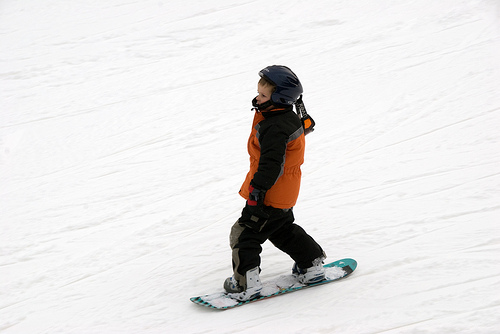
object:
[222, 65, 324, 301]
child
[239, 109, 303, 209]
coat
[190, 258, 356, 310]
snowboard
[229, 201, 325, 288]
pants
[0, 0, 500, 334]
mountain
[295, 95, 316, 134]
goggles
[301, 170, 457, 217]
tracks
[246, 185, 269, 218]
glove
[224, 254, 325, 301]
boots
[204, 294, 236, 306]
snow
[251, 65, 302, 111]
head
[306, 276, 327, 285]
clamp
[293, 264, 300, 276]
boot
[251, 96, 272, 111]
strap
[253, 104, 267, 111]
chin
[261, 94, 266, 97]
eye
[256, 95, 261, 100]
nose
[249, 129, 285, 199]
arm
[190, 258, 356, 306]
board